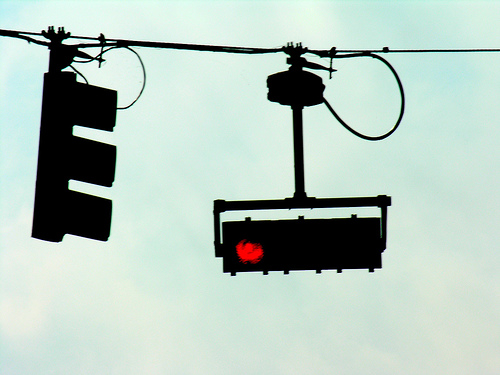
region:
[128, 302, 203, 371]
a cloud in the sky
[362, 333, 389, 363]
a cloud in the sky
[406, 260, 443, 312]
a cloud in the sky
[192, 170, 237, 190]
a cloud in the sky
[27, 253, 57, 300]
a cloud in the sky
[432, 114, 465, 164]
a cloud in the sky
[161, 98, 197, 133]
a cloud in the sky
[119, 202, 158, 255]
a cloud in the sky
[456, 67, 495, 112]
a cloud in the sky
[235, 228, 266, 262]
a red traffic light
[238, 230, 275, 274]
red light on pole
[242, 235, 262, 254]
black lines in the red light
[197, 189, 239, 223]
large base on the light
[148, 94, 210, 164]
clear blue clouds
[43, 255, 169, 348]
white clouds in the sky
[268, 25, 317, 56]
large black screws on the pole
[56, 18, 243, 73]
large black electrical line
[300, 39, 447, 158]
large black round wires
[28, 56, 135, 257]
large black electrical traffic light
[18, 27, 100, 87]
black base on electrical lights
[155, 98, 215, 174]
Sky is blue color.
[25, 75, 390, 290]
two traffic light is in picture.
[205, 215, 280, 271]
Red light is on.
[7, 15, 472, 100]
Power lines are running in air.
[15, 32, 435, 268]
Two lights are hanging from wire.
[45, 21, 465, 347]
Day time picture.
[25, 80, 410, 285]
Traffic lights are black color.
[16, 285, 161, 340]
Clouds are white color.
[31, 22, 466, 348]
Sky is clear with few clouds.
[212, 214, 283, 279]
One light is on.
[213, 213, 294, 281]
A red stoplight lit up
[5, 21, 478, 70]
Electric wire running across the sky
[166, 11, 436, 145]
A pale blue sky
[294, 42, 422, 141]
A cable running to a stoplight system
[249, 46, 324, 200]
The hanging connector for a stoplight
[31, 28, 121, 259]
The side view of a stoplight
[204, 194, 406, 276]
A horizontal stoplight system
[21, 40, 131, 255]
A vertical stoplight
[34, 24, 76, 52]
Bolts attaching a stoplight to wires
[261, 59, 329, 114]
A rotating piece on a stoplight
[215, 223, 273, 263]
The traffic light is red.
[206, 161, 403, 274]
The traffic light hanging from air.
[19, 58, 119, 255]
Another traffic light on the left.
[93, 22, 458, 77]
A wire to hold the traffic light.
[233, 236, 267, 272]
Light is a shiny red.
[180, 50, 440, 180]
the sky is blue.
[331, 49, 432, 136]
A cord is hanging from wire.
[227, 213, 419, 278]
Four slots on the traffic light.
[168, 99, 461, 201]
The sky is clear.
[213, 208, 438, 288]
The traffic light is shaped like a rectangle